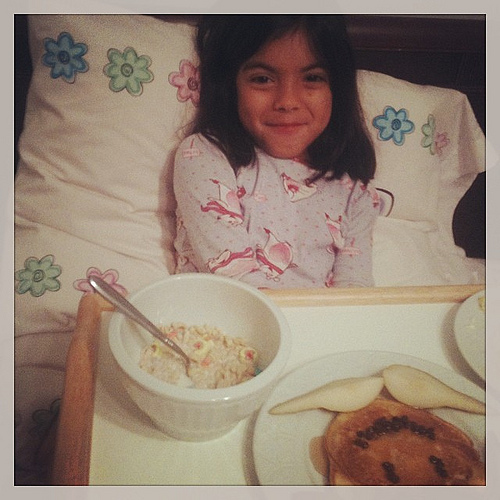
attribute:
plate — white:
[453, 290, 485, 382]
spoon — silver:
[87, 266, 211, 384]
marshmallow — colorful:
[242, 343, 257, 363]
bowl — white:
[103, 269, 295, 446]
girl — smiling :
[140, 36, 435, 363]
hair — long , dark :
[207, 25, 380, 182]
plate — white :
[247, 344, 487, 486]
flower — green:
[103, 46, 155, 98]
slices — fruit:
[283, 350, 457, 460]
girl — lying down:
[214, 50, 387, 196]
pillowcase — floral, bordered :
[22, 19, 240, 354]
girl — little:
[179, 25, 378, 284]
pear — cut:
[269, 360, 484, 416]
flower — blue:
[369, 102, 418, 146]